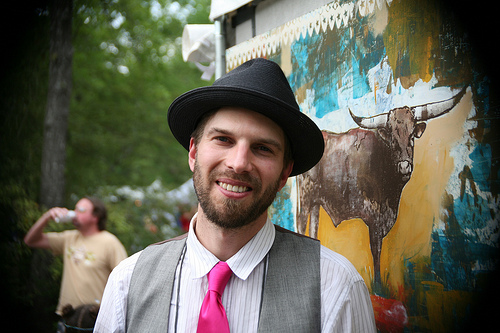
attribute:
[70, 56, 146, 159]
leaves — green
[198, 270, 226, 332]
tie — pink 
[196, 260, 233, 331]
pinktie — pink 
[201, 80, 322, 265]
man — white, man's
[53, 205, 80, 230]
can — silver 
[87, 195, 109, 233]
hair — brown 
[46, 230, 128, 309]
shirt — Beige 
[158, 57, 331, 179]
hat — black 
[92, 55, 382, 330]
man — smiling 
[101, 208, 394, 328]
shirt — tan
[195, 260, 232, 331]
tie — pink 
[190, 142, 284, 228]
beard — brown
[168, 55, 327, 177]
hat — black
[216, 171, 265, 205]
teeth — white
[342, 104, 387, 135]
horn — painted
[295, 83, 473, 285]
bull — painted